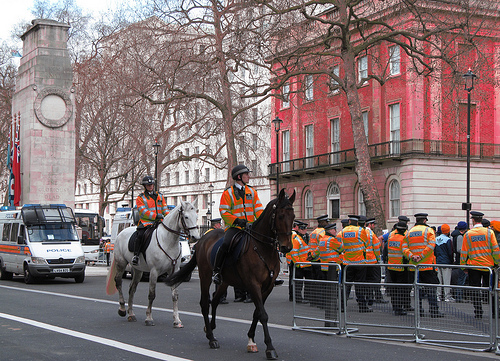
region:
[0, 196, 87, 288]
a police van with an orange stripe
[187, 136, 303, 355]
policeman on a brown horse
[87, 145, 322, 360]
two officers on horseback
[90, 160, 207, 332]
a policeman on a white horse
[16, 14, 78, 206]
a clock tower without a clock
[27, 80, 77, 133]
the round circle on the tower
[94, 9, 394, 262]
trees without any leaves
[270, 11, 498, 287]
the red building on the corner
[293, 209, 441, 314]
a group of policemen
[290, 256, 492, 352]
a metal fence baracade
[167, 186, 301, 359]
A brown horse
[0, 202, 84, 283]
A police van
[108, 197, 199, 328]
A white horse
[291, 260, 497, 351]
A metal barricade on the street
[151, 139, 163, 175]
A black streetlight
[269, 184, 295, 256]
The head of a brown horse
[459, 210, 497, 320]
A policeman wearing an orange vest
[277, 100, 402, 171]
Five rectangular windows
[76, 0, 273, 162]
Several trees with no leaves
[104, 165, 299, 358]
Two horses with policeman riding on them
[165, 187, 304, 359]
The brown horse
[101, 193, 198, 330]
The white horse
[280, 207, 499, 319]
The men standing in a group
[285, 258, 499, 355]
The barricade behind the men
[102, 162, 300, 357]
The two men on horses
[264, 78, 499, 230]
The red building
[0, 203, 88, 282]
The white and orange police van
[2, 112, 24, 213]
The flags next to the van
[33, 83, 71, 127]
The circle on the tower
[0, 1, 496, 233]
The trees without leaves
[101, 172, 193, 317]
police office on white horse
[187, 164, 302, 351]
police officer on brown horse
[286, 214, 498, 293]
group of police officers standing around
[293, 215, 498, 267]
police officers wearing orange vests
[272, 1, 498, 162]
red building behind officers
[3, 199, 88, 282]
police van behind officers on horses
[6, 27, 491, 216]
several buildings in the background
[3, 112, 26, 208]
several flags next to tower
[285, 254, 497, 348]
metal barrier gate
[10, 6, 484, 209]
several trees without leaves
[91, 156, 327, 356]
horse police officers in the city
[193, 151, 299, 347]
equestrian officer riding in the street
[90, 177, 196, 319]
police officer on a white horse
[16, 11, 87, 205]
stone tower with circular detail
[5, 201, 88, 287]
white bus with an orange stripe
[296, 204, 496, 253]
group of officers in orange vests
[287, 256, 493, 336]
metal crowd control fences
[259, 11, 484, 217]
brick building with windows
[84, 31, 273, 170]
bare trees in the wintertime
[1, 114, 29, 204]
flags against a tower